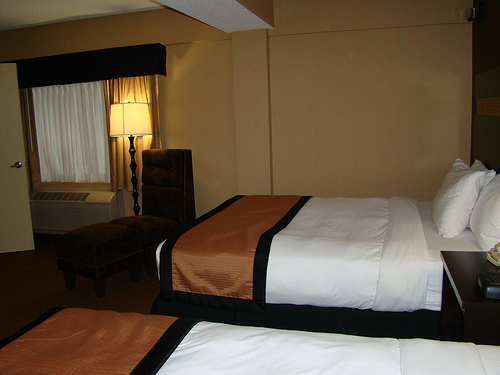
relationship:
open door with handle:
[2, 54, 47, 255] [7, 152, 27, 177]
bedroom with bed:
[0, 0, 500, 375] [154, 191, 484, 312]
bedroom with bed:
[0, 0, 500, 375] [0, 304, 497, 374]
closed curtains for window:
[30, 75, 162, 192] [75, 48, 179, 215]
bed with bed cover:
[156, 189, 498, 318] [159, 194, 430, 316]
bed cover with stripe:
[159, 194, 430, 316] [159, 188, 313, 305]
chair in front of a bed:
[94, 159, 204, 337] [162, 162, 495, 309]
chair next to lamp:
[55, 213, 183, 299] [74, 80, 214, 185]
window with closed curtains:
[33, 68, 115, 193] [30, 75, 162, 192]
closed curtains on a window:
[30, 75, 162, 192] [32, 64, 164, 196]